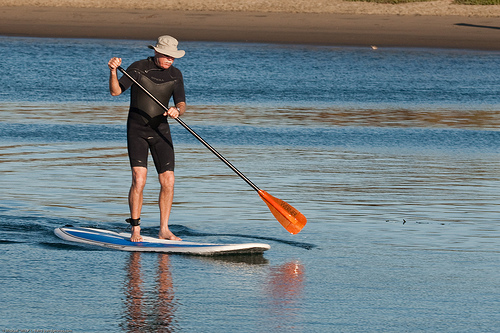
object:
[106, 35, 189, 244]
body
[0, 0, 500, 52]
sand shore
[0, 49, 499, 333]
water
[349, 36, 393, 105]
fence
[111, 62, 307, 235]
orange paddle